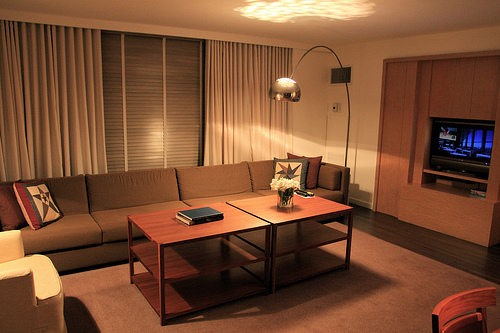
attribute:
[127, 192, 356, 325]
table — wooden, brown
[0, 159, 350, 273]
couch — long, brown, moder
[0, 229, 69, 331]
chair — yellow, cream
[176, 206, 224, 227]
book — blue, black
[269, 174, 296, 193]
flowers — white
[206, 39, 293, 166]
curtains — beige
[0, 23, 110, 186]
curtains — beige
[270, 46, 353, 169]
lamp — silver, curved, large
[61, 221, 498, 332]
carpet — brown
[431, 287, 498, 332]
chair — wood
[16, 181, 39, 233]
trim — red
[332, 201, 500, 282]
floor — wood